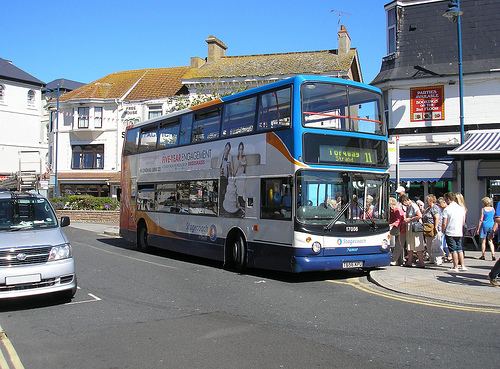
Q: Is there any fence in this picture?
A: No, there are no fences.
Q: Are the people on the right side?
A: Yes, the people are on the right of the image.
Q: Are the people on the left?
A: No, the people are on the right of the image.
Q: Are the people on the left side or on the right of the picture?
A: The people are on the right of the image.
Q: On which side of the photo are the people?
A: The people are on the right of the image.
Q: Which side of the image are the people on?
A: The people are on the right of the image.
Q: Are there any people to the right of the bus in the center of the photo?
A: Yes, there are people to the right of the bus.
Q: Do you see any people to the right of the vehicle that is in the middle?
A: Yes, there are people to the right of the bus.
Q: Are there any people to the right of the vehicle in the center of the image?
A: Yes, there are people to the right of the bus.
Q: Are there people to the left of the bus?
A: No, the people are to the right of the bus.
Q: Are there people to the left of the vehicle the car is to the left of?
A: No, the people are to the right of the bus.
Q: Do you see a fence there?
A: No, there are no fences.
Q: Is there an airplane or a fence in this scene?
A: No, there are no fences or airplanes.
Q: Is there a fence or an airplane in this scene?
A: No, there are no fences or airplanes.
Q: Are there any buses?
A: Yes, there is a bus.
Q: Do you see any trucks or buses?
A: Yes, there is a bus.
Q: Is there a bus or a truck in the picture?
A: Yes, there is a bus.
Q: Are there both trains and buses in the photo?
A: No, there is a bus but no trains.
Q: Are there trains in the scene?
A: No, there are no trains.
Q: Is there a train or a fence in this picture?
A: No, there are no trains or fences.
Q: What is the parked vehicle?
A: The vehicle is a bus.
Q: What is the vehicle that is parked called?
A: The vehicle is a bus.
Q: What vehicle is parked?
A: The vehicle is a bus.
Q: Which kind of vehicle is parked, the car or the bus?
A: The bus is parked.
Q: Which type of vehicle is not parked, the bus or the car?
A: The car is not parked.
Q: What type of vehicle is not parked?
A: The vehicle is a car.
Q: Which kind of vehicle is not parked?
A: The vehicle is a car.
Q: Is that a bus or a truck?
A: That is a bus.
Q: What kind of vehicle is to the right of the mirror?
A: The vehicle is a bus.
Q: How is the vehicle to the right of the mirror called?
A: The vehicle is a bus.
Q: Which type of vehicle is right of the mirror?
A: The vehicle is a bus.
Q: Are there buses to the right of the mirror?
A: Yes, there is a bus to the right of the mirror.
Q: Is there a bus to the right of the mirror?
A: Yes, there is a bus to the right of the mirror.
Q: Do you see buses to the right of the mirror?
A: Yes, there is a bus to the right of the mirror.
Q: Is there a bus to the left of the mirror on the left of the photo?
A: No, the bus is to the right of the mirror.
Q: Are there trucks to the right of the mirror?
A: No, there is a bus to the right of the mirror.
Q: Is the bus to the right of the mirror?
A: Yes, the bus is to the right of the mirror.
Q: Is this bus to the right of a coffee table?
A: No, the bus is to the right of the mirror.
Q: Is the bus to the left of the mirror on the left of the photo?
A: No, the bus is to the right of the mirror.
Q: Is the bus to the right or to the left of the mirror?
A: The bus is to the right of the mirror.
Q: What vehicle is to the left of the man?
A: The vehicle is a bus.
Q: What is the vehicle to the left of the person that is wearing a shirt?
A: The vehicle is a bus.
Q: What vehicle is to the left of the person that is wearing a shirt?
A: The vehicle is a bus.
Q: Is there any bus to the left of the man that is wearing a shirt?
A: Yes, there is a bus to the left of the man.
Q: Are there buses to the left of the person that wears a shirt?
A: Yes, there is a bus to the left of the man.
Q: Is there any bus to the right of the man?
A: No, the bus is to the left of the man.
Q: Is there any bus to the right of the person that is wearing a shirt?
A: No, the bus is to the left of the man.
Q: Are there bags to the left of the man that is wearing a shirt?
A: No, there is a bus to the left of the man.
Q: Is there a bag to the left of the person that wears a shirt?
A: No, there is a bus to the left of the man.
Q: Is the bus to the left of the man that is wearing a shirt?
A: Yes, the bus is to the left of the man.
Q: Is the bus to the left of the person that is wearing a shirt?
A: Yes, the bus is to the left of the man.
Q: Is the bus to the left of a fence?
A: No, the bus is to the left of the man.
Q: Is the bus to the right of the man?
A: No, the bus is to the left of the man.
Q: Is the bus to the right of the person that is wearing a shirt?
A: No, the bus is to the left of the man.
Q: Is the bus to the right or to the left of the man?
A: The bus is to the left of the man.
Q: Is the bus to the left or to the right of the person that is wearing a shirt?
A: The bus is to the left of the man.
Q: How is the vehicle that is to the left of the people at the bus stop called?
A: The vehicle is a bus.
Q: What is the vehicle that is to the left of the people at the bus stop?
A: The vehicle is a bus.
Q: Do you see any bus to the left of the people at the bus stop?
A: Yes, there is a bus to the left of the people.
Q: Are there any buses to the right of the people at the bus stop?
A: No, the bus is to the left of the people.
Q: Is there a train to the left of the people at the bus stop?
A: No, there is a bus to the left of the people.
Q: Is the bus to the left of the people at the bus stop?
A: Yes, the bus is to the left of the people.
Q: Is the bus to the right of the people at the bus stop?
A: No, the bus is to the left of the people.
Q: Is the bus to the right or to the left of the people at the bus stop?
A: The bus is to the left of the people.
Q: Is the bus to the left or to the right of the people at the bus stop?
A: The bus is to the left of the people.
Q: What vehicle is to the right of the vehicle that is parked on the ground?
A: The vehicle is a bus.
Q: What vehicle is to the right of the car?
A: The vehicle is a bus.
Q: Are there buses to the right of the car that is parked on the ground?
A: Yes, there is a bus to the right of the car.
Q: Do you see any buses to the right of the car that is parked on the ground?
A: Yes, there is a bus to the right of the car.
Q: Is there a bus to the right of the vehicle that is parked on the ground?
A: Yes, there is a bus to the right of the car.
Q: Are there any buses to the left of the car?
A: No, the bus is to the right of the car.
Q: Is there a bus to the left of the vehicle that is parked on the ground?
A: No, the bus is to the right of the car.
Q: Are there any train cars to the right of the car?
A: No, there is a bus to the right of the car.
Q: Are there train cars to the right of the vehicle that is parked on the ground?
A: No, there is a bus to the right of the car.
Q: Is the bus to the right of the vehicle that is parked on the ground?
A: Yes, the bus is to the right of the car.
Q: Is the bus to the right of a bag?
A: No, the bus is to the right of the car.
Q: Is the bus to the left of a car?
A: No, the bus is to the right of a car.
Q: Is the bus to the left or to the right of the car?
A: The bus is to the right of the car.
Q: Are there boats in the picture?
A: No, there are no boats.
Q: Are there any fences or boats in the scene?
A: No, there are no boats or fences.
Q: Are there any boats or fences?
A: No, there are no boats or fences.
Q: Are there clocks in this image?
A: No, there are no clocks.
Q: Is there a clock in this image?
A: No, there are no clocks.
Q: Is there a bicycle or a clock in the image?
A: No, there are no clocks or bicycles.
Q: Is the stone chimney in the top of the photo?
A: Yes, the chimney is in the top of the image.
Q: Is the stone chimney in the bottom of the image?
A: No, the chimney is in the top of the image.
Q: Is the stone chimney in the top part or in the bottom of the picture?
A: The chimney is in the top of the image.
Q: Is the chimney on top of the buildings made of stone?
A: Yes, the chimney is made of stone.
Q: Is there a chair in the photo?
A: No, there are no chairs.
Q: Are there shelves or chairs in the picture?
A: No, there are no chairs or shelves.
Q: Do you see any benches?
A: No, there are no benches.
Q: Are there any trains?
A: No, there are no trains.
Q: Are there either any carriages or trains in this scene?
A: No, there are no trains or carriages.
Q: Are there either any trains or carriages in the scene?
A: No, there are no trains or carriages.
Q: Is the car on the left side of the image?
A: Yes, the car is on the left of the image.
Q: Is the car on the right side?
A: No, the car is on the left of the image.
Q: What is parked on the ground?
A: The car is parked on the ground.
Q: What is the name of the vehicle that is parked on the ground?
A: The vehicle is a car.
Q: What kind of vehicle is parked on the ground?
A: The vehicle is a car.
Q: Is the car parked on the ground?
A: Yes, the car is parked on the ground.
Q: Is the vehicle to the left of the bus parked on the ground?
A: Yes, the car is parked on the ground.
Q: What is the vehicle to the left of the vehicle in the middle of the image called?
A: The vehicle is a car.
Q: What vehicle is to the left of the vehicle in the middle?
A: The vehicle is a car.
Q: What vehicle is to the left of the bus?
A: The vehicle is a car.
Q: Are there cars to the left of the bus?
A: Yes, there is a car to the left of the bus.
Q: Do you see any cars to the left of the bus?
A: Yes, there is a car to the left of the bus.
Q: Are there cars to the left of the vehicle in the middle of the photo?
A: Yes, there is a car to the left of the bus.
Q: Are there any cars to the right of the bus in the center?
A: No, the car is to the left of the bus.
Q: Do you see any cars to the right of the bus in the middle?
A: No, the car is to the left of the bus.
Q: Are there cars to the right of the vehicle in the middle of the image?
A: No, the car is to the left of the bus.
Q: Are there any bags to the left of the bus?
A: No, there is a car to the left of the bus.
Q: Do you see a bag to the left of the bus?
A: No, there is a car to the left of the bus.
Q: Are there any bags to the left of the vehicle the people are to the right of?
A: No, there is a car to the left of the bus.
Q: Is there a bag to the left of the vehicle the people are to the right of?
A: No, there is a car to the left of the bus.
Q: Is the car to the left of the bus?
A: Yes, the car is to the left of the bus.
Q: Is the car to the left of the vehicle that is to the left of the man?
A: Yes, the car is to the left of the bus.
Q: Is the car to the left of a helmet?
A: No, the car is to the left of the bus.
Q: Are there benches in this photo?
A: No, there are no benches.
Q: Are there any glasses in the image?
A: No, there are no glasses.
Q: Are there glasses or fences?
A: No, there are no glasses or fences.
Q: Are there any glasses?
A: No, there are no glasses.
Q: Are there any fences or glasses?
A: No, there are no glasses or fences.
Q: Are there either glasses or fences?
A: No, there are no glasses or fences.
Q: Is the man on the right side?
A: Yes, the man is on the right of the image.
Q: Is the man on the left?
A: No, the man is on the right of the image.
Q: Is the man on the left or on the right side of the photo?
A: The man is on the right of the image.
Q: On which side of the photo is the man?
A: The man is on the right of the image.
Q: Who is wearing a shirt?
A: The man is wearing a shirt.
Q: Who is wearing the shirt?
A: The man is wearing a shirt.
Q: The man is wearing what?
A: The man is wearing a shirt.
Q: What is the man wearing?
A: The man is wearing a shirt.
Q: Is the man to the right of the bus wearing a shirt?
A: Yes, the man is wearing a shirt.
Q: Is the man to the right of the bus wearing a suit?
A: No, the man is wearing a shirt.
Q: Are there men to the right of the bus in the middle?
A: Yes, there is a man to the right of the bus.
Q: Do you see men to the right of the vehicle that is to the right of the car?
A: Yes, there is a man to the right of the bus.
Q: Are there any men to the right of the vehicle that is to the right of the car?
A: Yes, there is a man to the right of the bus.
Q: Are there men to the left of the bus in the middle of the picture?
A: No, the man is to the right of the bus.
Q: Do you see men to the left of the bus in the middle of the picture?
A: No, the man is to the right of the bus.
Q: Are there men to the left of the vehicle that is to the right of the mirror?
A: No, the man is to the right of the bus.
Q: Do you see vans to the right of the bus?
A: No, there is a man to the right of the bus.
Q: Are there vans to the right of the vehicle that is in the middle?
A: No, there is a man to the right of the bus.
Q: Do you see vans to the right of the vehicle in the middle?
A: No, there is a man to the right of the bus.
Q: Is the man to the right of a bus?
A: Yes, the man is to the right of a bus.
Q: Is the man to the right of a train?
A: No, the man is to the right of a bus.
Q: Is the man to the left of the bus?
A: No, the man is to the right of the bus.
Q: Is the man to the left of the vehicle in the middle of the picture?
A: No, the man is to the right of the bus.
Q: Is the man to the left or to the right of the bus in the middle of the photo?
A: The man is to the right of the bus.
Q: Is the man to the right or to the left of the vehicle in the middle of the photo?
A: The man is to the right of the bus.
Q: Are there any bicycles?
A: No, there are no bicycles.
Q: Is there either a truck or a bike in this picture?
A: No, there are no bikes or trucks.